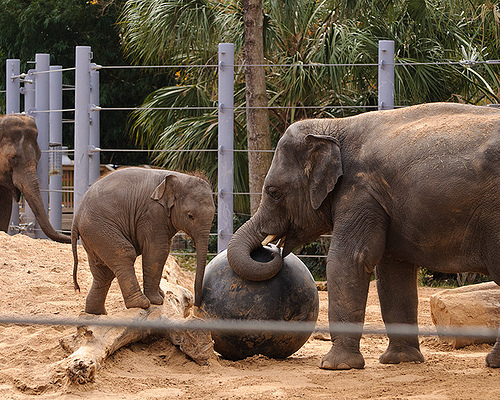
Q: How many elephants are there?
A: Three.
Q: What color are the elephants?
A: Gray.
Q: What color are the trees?
A: Green.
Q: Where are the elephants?
A: On the dirt.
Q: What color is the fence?
A: White and gray.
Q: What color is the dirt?
A: Brown.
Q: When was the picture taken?
A: Daytime.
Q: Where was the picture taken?
A: At the zoo.